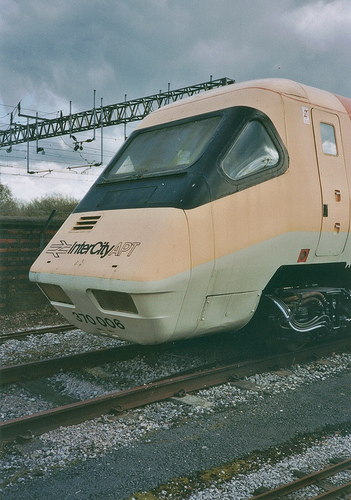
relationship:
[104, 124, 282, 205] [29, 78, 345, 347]
windshield on front of train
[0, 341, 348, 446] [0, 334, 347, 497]
tracks on ground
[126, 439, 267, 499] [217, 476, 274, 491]
moss by rocks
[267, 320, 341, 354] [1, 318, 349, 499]
wheels on track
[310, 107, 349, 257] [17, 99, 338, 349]
door on train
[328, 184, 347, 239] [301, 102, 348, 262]
handle on door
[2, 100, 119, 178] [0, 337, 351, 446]
wires above tracks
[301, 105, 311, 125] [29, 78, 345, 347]
sticker on train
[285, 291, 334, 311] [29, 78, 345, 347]
tubes under train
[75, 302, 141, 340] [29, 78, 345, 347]
numbers under train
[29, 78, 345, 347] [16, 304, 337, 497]
train on tracks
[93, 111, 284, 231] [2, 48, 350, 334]
window on front of train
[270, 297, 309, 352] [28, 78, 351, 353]
wheel on train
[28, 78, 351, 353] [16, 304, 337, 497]
train on tracks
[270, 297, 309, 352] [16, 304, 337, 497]
wheel on tracks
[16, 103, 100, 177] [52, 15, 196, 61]
power wires in sky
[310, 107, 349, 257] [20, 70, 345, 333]
door on train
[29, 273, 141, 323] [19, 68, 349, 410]
headlights on front of train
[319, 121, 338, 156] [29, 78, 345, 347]
side window on train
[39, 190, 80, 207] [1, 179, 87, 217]
leafs on trees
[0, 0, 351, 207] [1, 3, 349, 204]
clouds in sky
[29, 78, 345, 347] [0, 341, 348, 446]
train on tracks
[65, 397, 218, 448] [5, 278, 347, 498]
gravel on ground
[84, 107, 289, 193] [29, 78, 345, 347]
window on train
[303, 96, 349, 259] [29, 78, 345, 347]
door on train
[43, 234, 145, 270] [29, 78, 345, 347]
logo on train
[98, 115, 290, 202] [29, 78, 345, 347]
windshield on train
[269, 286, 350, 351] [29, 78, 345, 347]
wheel on train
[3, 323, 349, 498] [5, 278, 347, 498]
stones on ground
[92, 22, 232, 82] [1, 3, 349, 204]
clouds in sky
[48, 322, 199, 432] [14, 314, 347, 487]
metal on tracks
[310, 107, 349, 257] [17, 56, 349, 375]
door on train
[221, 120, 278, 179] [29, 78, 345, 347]
window of train